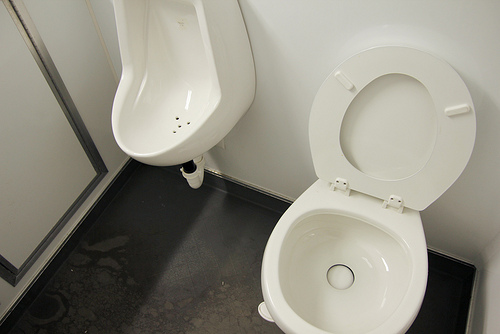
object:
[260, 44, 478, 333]
toilet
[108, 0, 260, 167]
urinal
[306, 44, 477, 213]
toilet seat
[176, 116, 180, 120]
hole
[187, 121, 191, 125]
hole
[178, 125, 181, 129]
hole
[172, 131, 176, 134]
hole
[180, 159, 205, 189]
pipe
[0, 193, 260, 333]
spots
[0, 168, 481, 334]
floor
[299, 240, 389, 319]
water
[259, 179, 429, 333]
toilet basin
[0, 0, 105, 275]
door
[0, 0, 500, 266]
wall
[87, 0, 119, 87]
caulk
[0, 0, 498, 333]
bathroom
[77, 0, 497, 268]
wall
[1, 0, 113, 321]
frame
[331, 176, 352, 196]
hinge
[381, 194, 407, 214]
hinge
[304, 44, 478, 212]
toilet lid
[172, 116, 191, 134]
drain